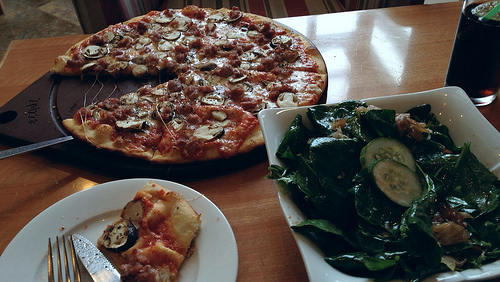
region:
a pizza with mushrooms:
[48, 5, 327, 158]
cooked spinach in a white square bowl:
[265, 88, 498, 275]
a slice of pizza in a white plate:
[93, 183, 197, 280]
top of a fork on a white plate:
[46, 230, 82, 280]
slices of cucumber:
[361, 136, 424, 206]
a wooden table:
[1, 3, 499, 278]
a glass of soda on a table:
[446, 2, 498, 109]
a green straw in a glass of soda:
[479, 0, 498, 22]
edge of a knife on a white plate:
[73, 231, 121, 280]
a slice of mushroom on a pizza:
[80, 45, 107, 60]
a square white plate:
[258, 86, 499, 278]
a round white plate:
[9, 173, 243, 281]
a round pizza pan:
[4, 4, 325, 184]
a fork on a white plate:
[39, 236, 84, 274]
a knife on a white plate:
[72, 228, 129, 278]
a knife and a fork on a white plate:
[48, 235, 110, 277]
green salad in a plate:
[276, 100, 496, 274]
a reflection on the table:
[283, 8, 418, 86]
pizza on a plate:
[107, 190, 202, 275]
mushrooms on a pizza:
[116, 118, 151, 133]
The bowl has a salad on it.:
[257, 85, 498, 280]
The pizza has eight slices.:
[57, 8, 325, 162]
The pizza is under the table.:
[62, 8, 326, 162]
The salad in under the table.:
[262, 87, 498, 281]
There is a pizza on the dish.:
[3, 177, 238, 280]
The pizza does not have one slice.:
[58, 7, 325, 162]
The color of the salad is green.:
[258, 87, 498, 280]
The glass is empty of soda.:
[445, 1, 499, 106]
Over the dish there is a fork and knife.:
[0, 179, 238, 280]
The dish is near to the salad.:
[0, 178, 239, 280]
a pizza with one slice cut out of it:
[39, 3, 333, 169]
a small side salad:
[250, 88, 499, 280]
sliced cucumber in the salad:
[361, 134, 428, 204]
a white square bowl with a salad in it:
[251, 83, 499, 280]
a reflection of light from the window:
[273, 3, 417, 102]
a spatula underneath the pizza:
[0, 131, 79, 159]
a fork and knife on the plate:
[45, 224, 127, 280]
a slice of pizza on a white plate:
[0, 172, 242, 280]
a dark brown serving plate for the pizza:
[0, 48, 335, 191]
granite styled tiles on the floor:
[0, 0, 84, 58]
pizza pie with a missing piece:
[0, 0, 332, 185]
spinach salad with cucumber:
[246, 74, 499, 280]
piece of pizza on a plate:
[1, 173, 245, 279]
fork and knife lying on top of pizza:
[38, 227, 122, 280]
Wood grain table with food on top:
[1, 0, 498, 280]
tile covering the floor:
[1, 0, 92, 63]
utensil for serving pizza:
[0, 133, 80, 160]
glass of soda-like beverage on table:
[440, 0, 495, 110]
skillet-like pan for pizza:
[0, 0, 339, 182]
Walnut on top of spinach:
[430, 217, 473, 252]